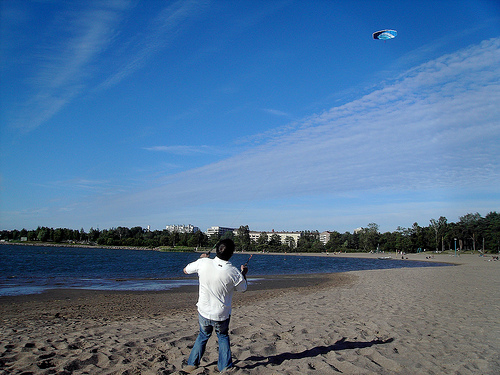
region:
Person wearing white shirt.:
[191, 236, 246, 353]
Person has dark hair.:
[213, 227, 263, 297]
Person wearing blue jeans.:
[178, 300, 250, 374]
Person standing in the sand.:
[157, 242, 245, 353]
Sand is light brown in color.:
[269, 252, 409, 370]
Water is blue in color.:
[61, 245, 162, 298]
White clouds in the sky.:
[206, 115, 466, 163]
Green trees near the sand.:
[301, 227, 493, 271]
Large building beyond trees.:
[161, 210, 328, 253]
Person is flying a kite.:
[363, 23, 481, 174]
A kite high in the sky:
[368, 26, 401, 43]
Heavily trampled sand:
[26, 300, 279, 373]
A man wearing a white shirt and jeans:
[183, 252, 256, 362]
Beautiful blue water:
[11, 245, 121, 270]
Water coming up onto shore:
[60, 275, 165, 310]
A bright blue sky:
[177, 37, 304, 92]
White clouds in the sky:
[290, 41, 482, 211]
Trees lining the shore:
[315, 210, 490, 251]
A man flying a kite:
[181, 193, 278, 344]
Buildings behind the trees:
[206, 221, 319, 248]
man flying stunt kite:
[177, 26, 395, 371]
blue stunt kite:
[362, 24, 402, 86]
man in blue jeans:
[177, 235, 257, 370]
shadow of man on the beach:
[230, 322, 402, 374]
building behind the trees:
[198, 222, 340, 251]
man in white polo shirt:
[184, 234, 251, 327]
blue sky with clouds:
[150, 79, 447, 197]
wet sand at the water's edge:
[8, 258, 177, 327]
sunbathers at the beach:
[377, 252, 445, 262]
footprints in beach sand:
[17, 326, 111, 374]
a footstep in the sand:
[26, 340, 43, 350]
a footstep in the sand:
[38, 352, 59, 358]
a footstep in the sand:
[33, 359, 65, 369]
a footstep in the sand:
[85, 349, 112, 368]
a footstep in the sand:
[107, 349, 129, 364]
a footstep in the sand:
[117, 337, 142, 347]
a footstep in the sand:
[303, 354, 328, 369]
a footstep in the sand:
[234, 320, 254, 336]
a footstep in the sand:
[173, 359, 191, 372]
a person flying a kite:
[171, 223, 266, 373]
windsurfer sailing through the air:
[362, 12, 424, 83]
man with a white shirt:
[172, 229, 271, 372]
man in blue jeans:
[169, 231, 261, 373]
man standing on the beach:
[178, 227, 273, 369]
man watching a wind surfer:
[174, 234, 259, 371]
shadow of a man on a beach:
[243, 324, 403, 366]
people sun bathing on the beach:
[377, 232, 497, 281]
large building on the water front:
[203, 218, 358, 250]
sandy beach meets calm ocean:
[22, 249, 138, 310]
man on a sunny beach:
[71, 200, 355, 340]